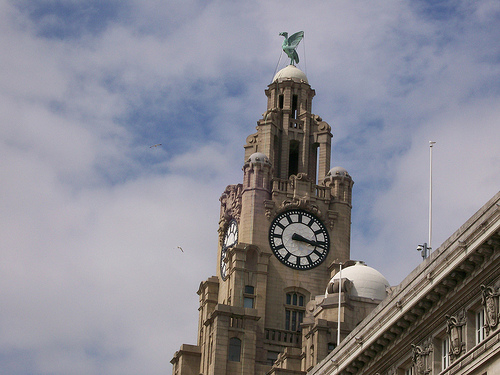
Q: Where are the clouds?
A: In the sky.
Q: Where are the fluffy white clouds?
A: Blue sky.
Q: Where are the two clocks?
A: Two sides clock tower.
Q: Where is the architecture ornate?
A: Below roof.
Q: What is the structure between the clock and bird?
A: Bell tower.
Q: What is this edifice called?
A: Clock tower.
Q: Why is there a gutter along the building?
A: Drain rain water.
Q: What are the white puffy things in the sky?
A: Clouds.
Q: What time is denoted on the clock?
A: 3:17PM.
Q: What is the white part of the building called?
A: Dome.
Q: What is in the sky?
A: Clouds.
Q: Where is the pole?
A: On the building.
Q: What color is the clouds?
A: White.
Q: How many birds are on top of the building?
A: One.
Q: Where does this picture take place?
A: Outside of a building.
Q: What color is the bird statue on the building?
A: Green.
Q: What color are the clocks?
A: Black and white.